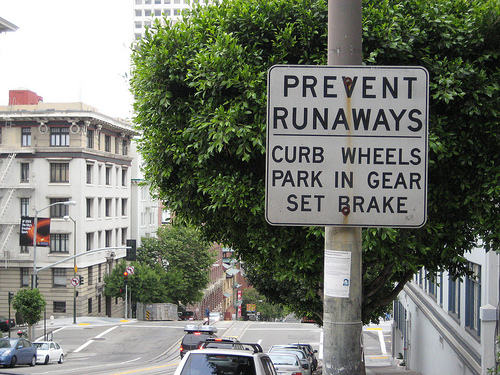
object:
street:
[0, 311, 393, 374]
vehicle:
[179, 323, 219, 363]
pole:
[320, 1, 364, 375]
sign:
[264, 62, 430, 229]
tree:
[129, 0, 499, 374]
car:
[32, 339, 68, 367]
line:
[33, 322, 119, 354]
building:
[0, 89, 145, 319]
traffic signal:
[123, 269, 129, 286]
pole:
[128, 282, 133, 319]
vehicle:
[173, 338, 280, 374]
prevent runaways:
[272, 74, 423, 133]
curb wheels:
[272, 145, 422, 165]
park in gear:
[272, 169, 422, 190]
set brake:
[286, 194, 409, 215]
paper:
[324, 249, 352, 299]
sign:
[125, 264, 136, 278]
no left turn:
[127, 266, 133, 274]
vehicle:
[0, 337, 38, 369]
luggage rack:
[202, 341, 265, 354]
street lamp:
[37, 199, 77, 213]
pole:
[125, 285, 128, 319]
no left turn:
[71, 279, 78, 286]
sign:
[71, 275, 80, 289]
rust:
[343, 76, 356, 135]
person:
[201, 306, 211, 327]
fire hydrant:
[49, 315, 55, 327]